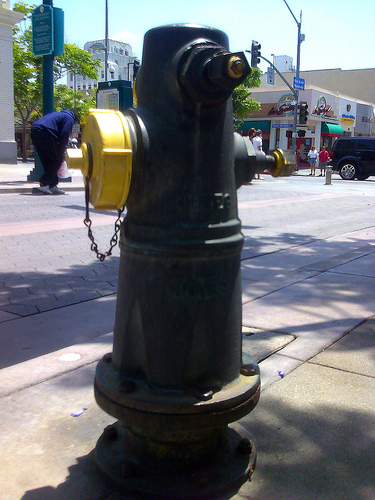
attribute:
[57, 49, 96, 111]
tree — leafy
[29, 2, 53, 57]
street sign — green, white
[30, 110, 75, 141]
shirt — blue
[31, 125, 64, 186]
pants — black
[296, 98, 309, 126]
traffic signal — black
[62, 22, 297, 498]
hydrant — metallic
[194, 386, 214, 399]
black bolt — black 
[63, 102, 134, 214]
stem — yellow 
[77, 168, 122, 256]
chain — black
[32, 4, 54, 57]
sign — blue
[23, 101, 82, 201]
pants — black